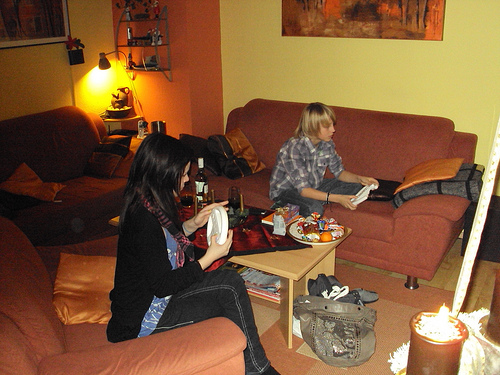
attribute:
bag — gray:
[289, 288, 379, 368]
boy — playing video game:
[268, 104, 353, 210]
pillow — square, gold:
[45, 245, 120, 329]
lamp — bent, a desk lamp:
[90, 45, 133, 70]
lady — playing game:
[71, 109, 292, 373]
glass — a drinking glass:
[227, 184, 240, 211]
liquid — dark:
[227, 197, 243, 209]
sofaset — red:
[204, 97, 473, 294]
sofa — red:
[186, 93, 479, 293]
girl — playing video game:
[133, 136, 261, 286]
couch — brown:
[185, 95, 477, 290]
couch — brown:
[0, 103, 148, 250]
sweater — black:
[103, 193, 206, 342]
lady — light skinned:
[102, 129, 280, 373]